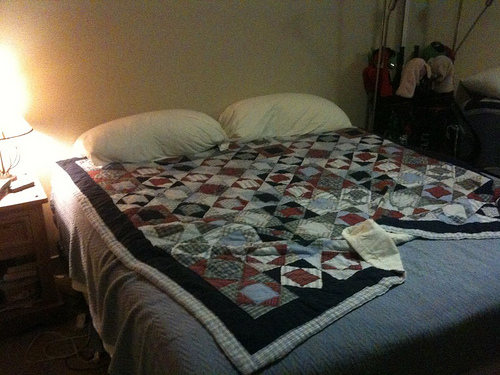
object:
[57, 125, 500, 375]
quilt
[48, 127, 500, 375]
bed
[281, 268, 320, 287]
design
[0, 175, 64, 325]
end table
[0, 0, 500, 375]
background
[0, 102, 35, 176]
lamp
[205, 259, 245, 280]
design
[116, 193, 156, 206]
design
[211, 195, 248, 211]
design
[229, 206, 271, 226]
design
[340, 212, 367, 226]
design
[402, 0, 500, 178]
mirror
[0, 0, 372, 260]
wall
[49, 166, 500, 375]
bedspread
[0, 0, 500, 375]
bedroom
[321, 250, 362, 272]
design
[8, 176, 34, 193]
book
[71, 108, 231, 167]
bed pillows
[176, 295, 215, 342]
edge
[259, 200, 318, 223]
design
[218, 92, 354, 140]
pillow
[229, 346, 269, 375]
corner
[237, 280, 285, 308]
design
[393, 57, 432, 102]
objects